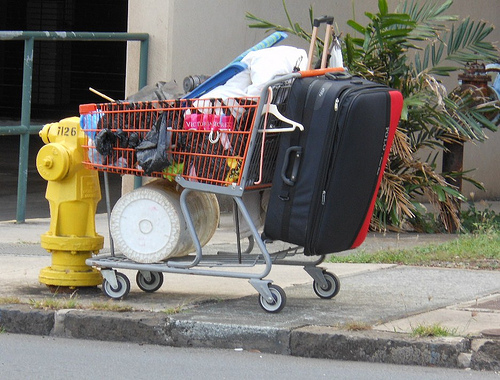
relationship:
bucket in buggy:
[107, 179, 203, 268] [72, 75, 398, 346]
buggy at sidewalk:
[72, 75, 398, 346] [15, 242, 487, 359]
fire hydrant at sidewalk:
[32, 111, 102, 296] [15, 242, 487, 359]